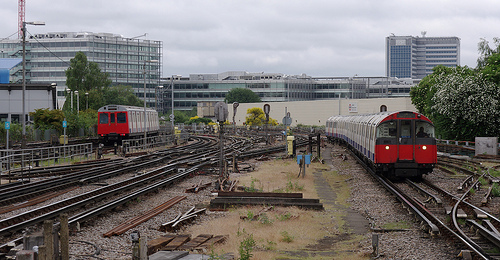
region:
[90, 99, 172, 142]
A train with a red front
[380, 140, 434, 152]
Headlights on a train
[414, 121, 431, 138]
A train conductor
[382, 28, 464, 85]
A large building in the distance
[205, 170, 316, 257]
Patches of green shrubs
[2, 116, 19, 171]
A blue sign and post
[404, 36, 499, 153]
A patch of trees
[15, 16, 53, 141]
A tall light pole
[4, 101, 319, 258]
A large group of train tracks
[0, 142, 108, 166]
A small metal fence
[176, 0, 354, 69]
this is the sky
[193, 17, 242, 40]
these are the clouds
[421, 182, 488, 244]
these are the railway lines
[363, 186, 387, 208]
these are small rocks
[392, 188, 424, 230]
this is a metal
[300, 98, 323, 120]
this is a wall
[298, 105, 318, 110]
the wall is white in color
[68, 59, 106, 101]
this is a tree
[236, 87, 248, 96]
the tree has green leaves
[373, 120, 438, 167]
front of train on the right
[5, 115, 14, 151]
blue sign on the left front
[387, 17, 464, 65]
tall building on right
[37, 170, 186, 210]
tracks in middle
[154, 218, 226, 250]
wood slates on ground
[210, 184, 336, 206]
steel slates on the dirt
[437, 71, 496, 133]
tree on the right side of train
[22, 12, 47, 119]
silvver light ppole on left front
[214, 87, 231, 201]
sign in front steel slates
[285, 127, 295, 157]
yellow pole in betweentracks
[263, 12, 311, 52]
part of some cloud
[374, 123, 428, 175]
front of a train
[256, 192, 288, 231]
part of a grass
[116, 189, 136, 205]
edge of a train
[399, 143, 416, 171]
part of a door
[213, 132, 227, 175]
part of a post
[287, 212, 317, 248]
part of a ground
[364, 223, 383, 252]
part of a post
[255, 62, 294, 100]
part of a building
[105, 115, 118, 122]
part of a window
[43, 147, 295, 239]
There are a lot of train tracks here.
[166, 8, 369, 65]
Cloudy skies in the background.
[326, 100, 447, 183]
The train's front is red.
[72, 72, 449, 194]
There are two trains.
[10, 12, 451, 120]
Buildings can be seen in the background.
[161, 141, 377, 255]
There is grass and debris between the tracks.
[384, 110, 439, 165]
A person is inside the train.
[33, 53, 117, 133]
Trees can be seen.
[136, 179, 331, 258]
Some parts look rusty.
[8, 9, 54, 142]
A lamp post.